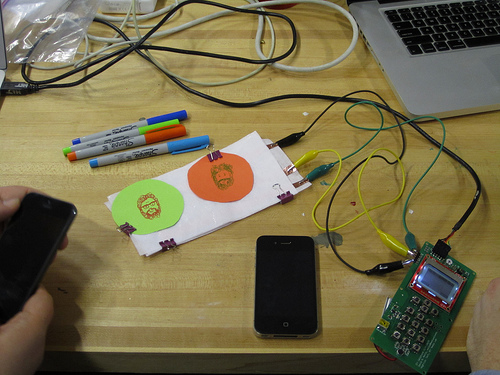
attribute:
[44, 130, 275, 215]
markers — colorful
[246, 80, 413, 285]
cord — black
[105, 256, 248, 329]
desk — brown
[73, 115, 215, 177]
markers — assorted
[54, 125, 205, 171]
markers — assorted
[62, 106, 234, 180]
markers — assorted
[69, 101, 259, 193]
markers — assorted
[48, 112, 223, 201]
markers — assorted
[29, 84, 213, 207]
markers — assorted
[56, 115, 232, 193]
markers — assorted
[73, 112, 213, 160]
markers — assorted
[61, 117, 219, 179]
markers — assorted